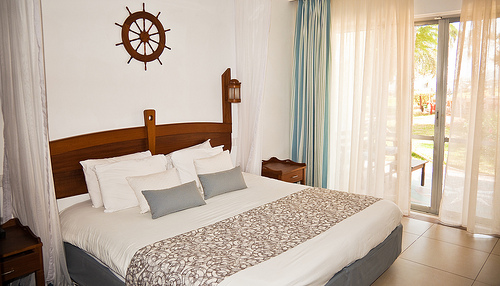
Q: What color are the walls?
A: White.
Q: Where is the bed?
A: In the room.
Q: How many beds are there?
A: One.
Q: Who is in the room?
A: No one.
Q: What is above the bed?
A: A wheel.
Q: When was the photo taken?
A: Daytime.